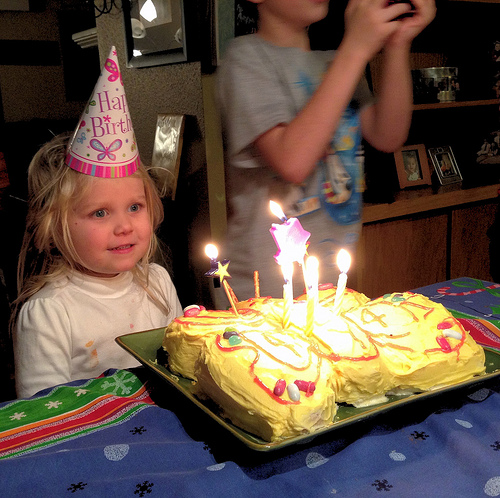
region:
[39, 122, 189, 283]
head of a person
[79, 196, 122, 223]
eye of a person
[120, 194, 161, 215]
eye of a person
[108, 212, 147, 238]
nose of a person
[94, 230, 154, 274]
mouth of a person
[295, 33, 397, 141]
arm of a person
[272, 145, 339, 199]
elbow of a person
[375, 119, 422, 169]
elbow of a person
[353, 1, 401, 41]
hand of a person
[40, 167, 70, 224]
hair of a person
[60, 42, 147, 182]
A girl is wearing a birthday hat.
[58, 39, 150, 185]
The colors of a hat are pink, green, yellow, blue, and white.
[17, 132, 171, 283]
A girl is smiling.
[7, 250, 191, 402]
A girl is wearing a white and yellow top.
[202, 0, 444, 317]
A person is taking a picture.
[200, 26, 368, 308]
A person is wearing a mostly gray shirt.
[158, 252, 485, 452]
A birthday cake is sitting on a platter.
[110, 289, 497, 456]
The color of a platter is green.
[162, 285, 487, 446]
The colors of a cake are yellow, red, white, and green.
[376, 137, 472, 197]
Pictures are on a shelf.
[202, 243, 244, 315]
Birthday candle lit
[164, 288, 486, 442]
yellow icing on a cake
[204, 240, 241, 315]
A candle with a star on it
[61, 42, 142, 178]
A happy birthday hat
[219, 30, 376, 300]
A gray shirt being worn by a kid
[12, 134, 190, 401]
A little girl wearing a white shirt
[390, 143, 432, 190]
Picture in a frame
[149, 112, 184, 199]
A frame on a wall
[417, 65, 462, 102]
A silver picture frame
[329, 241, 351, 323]
Plain lit candle on a cake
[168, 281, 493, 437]
A birthday cake on the serving tray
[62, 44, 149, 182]
A pink birthday hat on the girl's head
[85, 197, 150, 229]
The girl's eyes are open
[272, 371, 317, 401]
Large sprinkles on the birthday cake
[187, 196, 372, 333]
Candles on the cake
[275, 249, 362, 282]
The candles are on fire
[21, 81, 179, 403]
The child is about to blow out the candles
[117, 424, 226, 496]
A blue tablecloth beneath the cake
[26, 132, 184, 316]
The girl has long blonde hair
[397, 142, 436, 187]
A picture frame on the shelf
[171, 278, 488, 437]
Big yellow birthday cake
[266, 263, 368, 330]
Yellow lit birthday candles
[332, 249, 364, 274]
Fire on a birthday candle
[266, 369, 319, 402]
Jelly beans on a birthday cake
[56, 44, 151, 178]
Pink birthday cone hat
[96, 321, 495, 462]
Green platter on a table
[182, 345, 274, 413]
Yellow frosting on a birthday cake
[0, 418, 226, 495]
Colorful tablecloth on the table